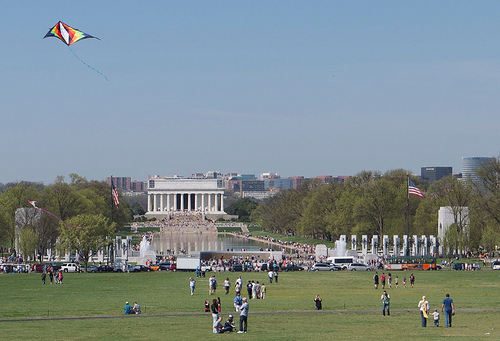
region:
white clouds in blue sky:
[185, 53, 240, 108]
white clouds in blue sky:
[86, 81, 161, 119]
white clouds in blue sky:
[317, 68, 371, 134]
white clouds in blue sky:
[219, 36, 257, 70]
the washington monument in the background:
[105, 160, 248, 242]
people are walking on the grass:
[320, 251, 465, 329]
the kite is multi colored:
[7, 3, 130, 88]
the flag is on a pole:
[387, 156, 444, 237]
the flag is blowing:
[371, 148, 435, 222]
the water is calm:
[94, 202, 287, 274]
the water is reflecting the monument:
[139, 222, 238, 252]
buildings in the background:
[60, 135, 363, 211]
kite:
[41, 14, 92, 52]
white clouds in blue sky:
[339, 70, 427, 168]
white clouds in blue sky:
[251, 107, 276, 117]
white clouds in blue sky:
[135, 132, 158, 149]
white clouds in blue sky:
[221, 32, 268, 100]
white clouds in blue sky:
[242, 9, 302, 48]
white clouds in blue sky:
[375, 82, 422, 115]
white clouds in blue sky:
[215, 34, 286, 81]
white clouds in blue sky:
[220, 114, 277, 148]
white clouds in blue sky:
[161, 74, 222, 121]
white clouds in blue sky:
[118, 93, 192, 134]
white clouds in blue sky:
[256, 57, 309, 96]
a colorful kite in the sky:
[38, 12, 105, 69]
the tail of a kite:
[60, 33, 101, 85]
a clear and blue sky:
[151, 48, 245, 128]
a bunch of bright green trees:
[51, 192, 93, 237]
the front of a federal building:
[140, 171, 228, 218]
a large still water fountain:
[147, 215, 221, 263]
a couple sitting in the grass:
[114, 296, 152, 320]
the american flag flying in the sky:
[394, 172, 438, 219]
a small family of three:
[411, 265, 468, 333]